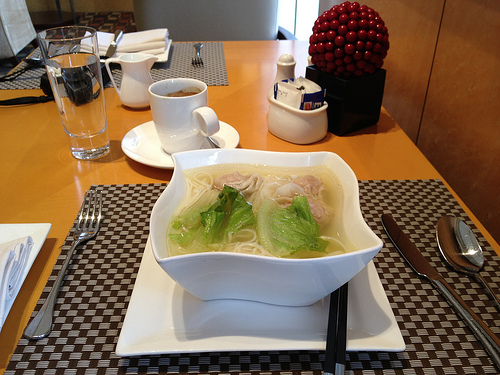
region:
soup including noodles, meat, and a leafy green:
[192, 172, 325, 248]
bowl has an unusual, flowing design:
[148, 148, 383, 308]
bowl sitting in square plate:
[116, 171, 403, 368]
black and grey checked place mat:
[10, 176, 495, 373]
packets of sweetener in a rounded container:
[265, 79, 329, 146]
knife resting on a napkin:
[86, 28, 169, 62]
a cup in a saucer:
[122, 78, 241, 161]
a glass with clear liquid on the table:
[31, 25, 133, 172]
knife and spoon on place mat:
[376, 176, 498, 361]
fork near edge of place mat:
[23, 184, 108, 354]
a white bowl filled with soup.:
[141, 150, 388, 316]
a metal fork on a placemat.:
[20, 196, 115, 345]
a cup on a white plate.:
[141, 65, 226, 153]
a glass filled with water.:
[44, 25, 117, 165]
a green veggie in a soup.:
[167, 170, 254, 250]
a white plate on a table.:
[107, 211, 417, 358]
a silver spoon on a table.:
[410, 197, 495, 285]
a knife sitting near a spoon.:
[373, 210, 498, 360]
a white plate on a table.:
[0, 211, 73, 341]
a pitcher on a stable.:
[90, 30, 162, 117]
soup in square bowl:
[163, 150, 380, 300]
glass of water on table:
[38, 25, 110, 160]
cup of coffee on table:
[134, 74, 220, 139]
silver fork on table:
[30, 185, 109, 347]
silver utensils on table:
[373, 198, 499, 368]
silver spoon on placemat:
[427, 215, 499, 287]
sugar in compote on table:
[265, 72, 325, 139]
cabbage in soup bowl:
[248, 197, 316, 251]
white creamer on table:
[113, 47, 151, 107]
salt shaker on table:
[260, 50, 300, 73]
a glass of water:
[37, 18, 117, 164]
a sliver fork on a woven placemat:
[16, 183, 108, 350]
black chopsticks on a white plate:
[103, 262, 414, 372]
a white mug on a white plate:
[112, 71, 232, 172]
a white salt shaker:
[266, 48, 301, 87]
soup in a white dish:
[147, 149, 388, 275]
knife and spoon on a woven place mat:
[367, 175, 498, 374]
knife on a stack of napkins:
[73, 20, 173, 61]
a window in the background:
[274, 0, 321, 44]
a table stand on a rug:
[31, 0, 138, 46]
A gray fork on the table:
[23, 202, 106, 338]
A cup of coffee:
[140, 72, 226, 154]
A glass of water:
[34, 18, 118, 160]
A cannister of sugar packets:
[269, 74, 333, 145]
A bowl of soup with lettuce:
[148, 142, 388, 314]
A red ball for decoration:
[303, 0, 395, 139]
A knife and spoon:
[373, 190, 498, 366]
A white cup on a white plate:
[127, 69, 236, 168]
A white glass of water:
[33, 29, 117, 163]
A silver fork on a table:
[18, 189, 105, 333]